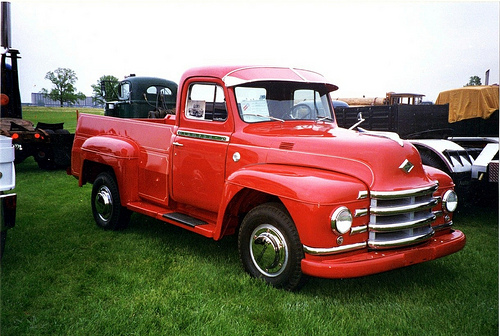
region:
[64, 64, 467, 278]
old red truck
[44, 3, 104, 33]
white clouds in blue sky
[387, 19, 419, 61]
white clouds in blue sky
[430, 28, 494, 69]
white clouds in blue sky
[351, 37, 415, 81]
white clouds in blue sky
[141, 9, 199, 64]
white clouds in blue sky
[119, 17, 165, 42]
white clouds in blue sky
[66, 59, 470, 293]
a red truck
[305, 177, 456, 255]
grill on front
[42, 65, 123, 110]
trees in back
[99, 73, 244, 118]
a black truck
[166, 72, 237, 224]
door to red truck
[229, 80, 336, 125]
windshield to red vehicle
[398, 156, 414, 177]
emblem on truck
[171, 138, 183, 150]
handle to door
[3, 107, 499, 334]
the green grass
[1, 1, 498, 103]
a clear sky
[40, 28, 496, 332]
this is a truck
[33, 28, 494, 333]
this is a classic styled truck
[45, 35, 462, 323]
the truck is red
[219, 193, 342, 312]
black tire on truck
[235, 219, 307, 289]
chrome rim on truck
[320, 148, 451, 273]
chrome grill on truck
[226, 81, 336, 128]
front windshield of truck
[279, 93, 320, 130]
steering wheel on truck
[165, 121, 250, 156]
silver trim on door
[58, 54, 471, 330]
truck parked on grass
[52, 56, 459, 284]
old red truck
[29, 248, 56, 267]
long green and yellow grass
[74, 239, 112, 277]
long green and yellow grass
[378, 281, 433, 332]
long green and yellow grass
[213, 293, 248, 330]
long green and yellow grass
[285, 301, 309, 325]
long green and yellow grass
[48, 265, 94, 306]
long green and yellow grass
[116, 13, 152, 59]
white clouds in blue sky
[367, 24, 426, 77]
white clouds in blue sky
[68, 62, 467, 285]
a red pick up truck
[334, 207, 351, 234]
a front right headlight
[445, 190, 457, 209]
a front left headlight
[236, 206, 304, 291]
a front right tire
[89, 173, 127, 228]
a right right headlight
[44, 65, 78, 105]
large green tree in distance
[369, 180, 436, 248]
a chrome radiator grill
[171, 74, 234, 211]
a right red door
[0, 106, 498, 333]
a green grassy field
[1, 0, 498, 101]
a white overcast sky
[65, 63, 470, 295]
A RED PICKUP TRUCK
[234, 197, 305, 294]
A FRONT TRUCK TIRE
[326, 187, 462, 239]
TWO TRUCK HEADLIGHTS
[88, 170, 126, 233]
A REAR TRUCK TIRE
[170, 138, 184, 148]
A TRUCK DOOR HANDLE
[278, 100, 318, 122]
A TRUCKS STEERING WHEEL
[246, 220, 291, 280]
A METAL HUBCAP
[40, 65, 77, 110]
A TREE IN THE DISTANCE